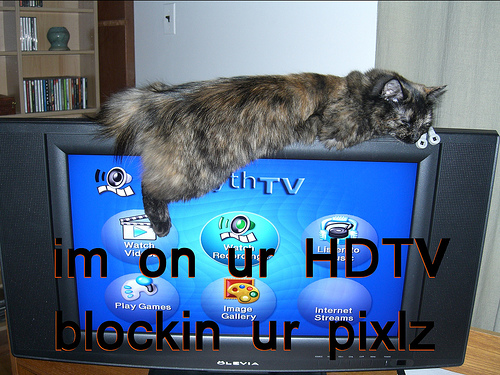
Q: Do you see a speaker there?
A: Yes, there is a speaker.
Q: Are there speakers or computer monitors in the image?
A: Yes, there is a speaker.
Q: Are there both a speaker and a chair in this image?
A: No, there is a speaker but no chairs.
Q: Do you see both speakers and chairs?
A: No, there is a speaker but no chairs.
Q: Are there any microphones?
A: No, there are no microphones.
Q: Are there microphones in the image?
A: No, there are no microphones.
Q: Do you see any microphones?
A: No, there are no microphones.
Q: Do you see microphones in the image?
A: No, there are no microphones.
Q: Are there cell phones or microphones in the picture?
A: No, there are no microphones or cell phones.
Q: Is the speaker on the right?
A: Yes, the speaker is on the right of the image.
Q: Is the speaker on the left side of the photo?
A: No, the speaker is on the right of the image.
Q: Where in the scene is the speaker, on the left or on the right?
A: The speaker is on the right of the image.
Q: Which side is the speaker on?
A: The speaker is on the right of the image.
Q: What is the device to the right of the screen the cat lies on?
A: The device is a speaker.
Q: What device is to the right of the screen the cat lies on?
A: The device is a speaker.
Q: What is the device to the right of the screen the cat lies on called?
A: The device is a speaker.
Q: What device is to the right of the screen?
A: The device is a speaker.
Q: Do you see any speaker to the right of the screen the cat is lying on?
A: Yes, there is a speaker to the right of the screen.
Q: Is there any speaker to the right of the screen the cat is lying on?
A: Yes, there is a speaker to the right of the screen.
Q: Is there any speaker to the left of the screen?
A: No, the speaker is to the right of the screen.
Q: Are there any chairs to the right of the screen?
A: No, there is a speaker to the right of the screen.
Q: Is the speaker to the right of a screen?
A: Yes, the speaker is to the right of a screen.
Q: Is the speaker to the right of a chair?
A: No, the speaker is to the right of a screen.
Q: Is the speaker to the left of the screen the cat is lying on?
A: No, the speaker is to the right of the screen.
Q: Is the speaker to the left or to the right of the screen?
A: The speaker is to the right of the screen.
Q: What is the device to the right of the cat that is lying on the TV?
A: The device is a speaker.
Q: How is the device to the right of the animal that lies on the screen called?
A: The device is a speaker.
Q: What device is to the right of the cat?
A: The device is a speaker.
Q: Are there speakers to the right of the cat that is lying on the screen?
A: Yes, there is a speaker to the right of the cat.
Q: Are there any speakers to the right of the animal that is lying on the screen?
A: Yes, there is a speaker to the right of the cat.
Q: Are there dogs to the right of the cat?
A: No, there is a speaker to the right of the cat.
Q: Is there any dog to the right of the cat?
A: No, there is a speaker to the right of the cat.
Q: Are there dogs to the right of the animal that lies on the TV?
A: No, there is a speaker to the right of the cat.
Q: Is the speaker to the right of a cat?
A: Yes, the speaker is to the right of a cat.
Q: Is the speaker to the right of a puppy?
A: No, the speaker is to the right of a cat.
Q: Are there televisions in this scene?
A: Yes, there is a television.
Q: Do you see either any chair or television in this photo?
A: Yes, there is a television.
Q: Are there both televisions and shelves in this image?
A: Yes, there are both a television and a shelf.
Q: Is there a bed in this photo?
A: No, there are no beds.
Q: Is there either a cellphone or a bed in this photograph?
A: No, there are no beds or cell phones.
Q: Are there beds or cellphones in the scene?
A: No, there are no beds or cellphones.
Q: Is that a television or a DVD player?
A: That is a television.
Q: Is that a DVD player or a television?
A: That is a television.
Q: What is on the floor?
A: The television is on the floor.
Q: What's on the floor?
A: The television is on the floor.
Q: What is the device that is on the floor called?
A: The device is a television.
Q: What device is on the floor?
A: The device is a television.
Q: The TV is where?
A: The TV is on the floor.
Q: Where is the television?
A: The TV is on the floor.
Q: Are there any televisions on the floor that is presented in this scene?
A: Yes, there is a television on the floor.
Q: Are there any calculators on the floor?
A: No, there is a television on the floor.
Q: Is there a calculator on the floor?
A: No, there is a television on the floor.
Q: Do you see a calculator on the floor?
A: No, there is a television on the floor.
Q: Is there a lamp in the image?
A: No, there are no lamps.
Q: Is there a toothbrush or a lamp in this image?
A: No, there are no lamps or toothbrushes.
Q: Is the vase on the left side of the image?
A: Yes, the vase is on the left of the image.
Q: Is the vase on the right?
A: No, the vase is on the left of the image.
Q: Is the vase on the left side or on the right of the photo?
A: The vase is on the left of the image.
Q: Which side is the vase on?
A: The vase is on the left of the image.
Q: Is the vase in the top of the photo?
A: Yes, the vase is in the top of the image.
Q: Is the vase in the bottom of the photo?
A: No, the vase is in the top of the image.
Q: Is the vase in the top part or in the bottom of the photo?
A: The vase is in the top of the image.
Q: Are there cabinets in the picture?
A: No, there are no cabinets.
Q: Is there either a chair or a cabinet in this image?
A: No, there are no cabinets or chairs.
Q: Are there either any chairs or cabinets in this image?
A: No, there are no cabinets or chairs.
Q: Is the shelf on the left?
A: Yes, the shelf is on the left of the image.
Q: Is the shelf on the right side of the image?
A: No, the shelf is on the left of the image.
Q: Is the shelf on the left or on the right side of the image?
A: The shelf is on the left of the image.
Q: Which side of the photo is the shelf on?
A: The shelf is on the left of the image.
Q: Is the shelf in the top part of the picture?
A: Yes, the shelf is in the top of the image.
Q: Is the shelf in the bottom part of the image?
A: No, the shelf is in the top of the image.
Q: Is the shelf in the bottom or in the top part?
A: The shelf is in the top of the image.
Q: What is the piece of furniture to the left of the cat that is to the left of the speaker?
A: The piece of furniture is a shelf.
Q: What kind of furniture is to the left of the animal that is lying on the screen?
A: The piece of furniture is a shelf.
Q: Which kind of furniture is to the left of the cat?
A: The piece of furniture is a shelf.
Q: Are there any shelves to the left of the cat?
A: Yes, there is a shelf to the left of the cat.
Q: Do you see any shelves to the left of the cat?
A: Yes, there is a shelf to the left of the cat.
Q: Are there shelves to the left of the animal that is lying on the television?
A: Yes, there is a shelf to the left of the cat.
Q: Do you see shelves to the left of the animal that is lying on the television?
A: Yes, there is a shelf to the left of the cat.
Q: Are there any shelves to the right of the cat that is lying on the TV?
A: No, the shelf is to the left of the cat.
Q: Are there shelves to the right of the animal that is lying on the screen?
A: No, the shelf is to the left of the cat.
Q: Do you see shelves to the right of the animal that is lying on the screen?
A: No, the shelf is to the left of the cat.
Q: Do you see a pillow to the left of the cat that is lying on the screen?
A: No, there is a shelf to the left of the cat.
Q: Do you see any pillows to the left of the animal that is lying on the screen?
A: No, there is a shelf to the left of the cat.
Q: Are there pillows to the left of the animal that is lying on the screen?
A: No, there is a shelf to the left of the cat.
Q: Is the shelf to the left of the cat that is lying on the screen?
A: Yes, the shelf is to the left of the cat.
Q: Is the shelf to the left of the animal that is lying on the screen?
A: Yes, the shelf is to the left of the cat.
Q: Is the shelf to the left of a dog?
A: No, the shelf is to the left of the cat.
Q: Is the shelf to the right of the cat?
A: No, the shelf is to the left of the cat.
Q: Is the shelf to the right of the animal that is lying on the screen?
A: No, the shelf is to the left of the cat.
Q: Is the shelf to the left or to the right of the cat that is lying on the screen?
A: The shelf is to the left of the cat.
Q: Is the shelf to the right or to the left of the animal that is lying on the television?
A: The shelf is to the left of the cat.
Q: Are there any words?
A: Yes, there are words.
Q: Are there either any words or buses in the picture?
A: Yes, there are words.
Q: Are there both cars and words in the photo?
A: No, there are words but no cars.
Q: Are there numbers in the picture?
A: No, there are no numbers.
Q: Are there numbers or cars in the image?
A: No, there are no numbers or cars.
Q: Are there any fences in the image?
A: No, there are no fences.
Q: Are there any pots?
A: No, there are no pots.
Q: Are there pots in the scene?
A: No, there are no pots.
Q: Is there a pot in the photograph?
A: No, there are no pots.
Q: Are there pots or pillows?
A: No, there are no pots or pillows.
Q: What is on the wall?
A: The switch is on the wall.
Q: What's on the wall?
A: The switch is on the wall.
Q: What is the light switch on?
A: The light switch is on the wall.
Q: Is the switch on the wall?
A: Yes, the switch is on the wall.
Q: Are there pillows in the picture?
A: No, there are no pillows.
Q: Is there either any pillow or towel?
A: No, there are no pillows or towels.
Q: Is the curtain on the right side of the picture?
A: Yes, the curtain is on the right of the image.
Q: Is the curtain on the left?
A: No, the curtain is on the right of the image.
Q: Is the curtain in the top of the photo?
A: Yes, the curtain is in the top of the image.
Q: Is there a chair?
A: No, there are no chairs.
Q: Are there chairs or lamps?
A: No, there are no chairs or lamps.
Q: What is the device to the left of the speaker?
A: The device is a screen.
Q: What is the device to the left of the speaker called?
A: The device is a screen.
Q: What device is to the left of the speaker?
A: The device is a screen.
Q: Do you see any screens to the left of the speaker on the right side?
A: Yes, there is a screen to the left of the speaker.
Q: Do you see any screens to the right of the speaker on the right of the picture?
A: No, the screen is to the left of the speaker.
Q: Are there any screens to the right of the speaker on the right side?
A: No, the screen is to the left of the speaker.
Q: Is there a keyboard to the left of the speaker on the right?
A: No, there is a screen to the left of the speaker.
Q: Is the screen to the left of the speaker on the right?
A: Yes, the screen is to the left of the speaker.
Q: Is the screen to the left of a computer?
A: No, the screen is to the left of the speaker.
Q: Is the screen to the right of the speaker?
A: No, the screen is to the left of the speaker.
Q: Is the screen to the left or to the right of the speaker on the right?
A: The screen is to the left of the speaker.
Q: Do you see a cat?
A: Yes, there is a cat.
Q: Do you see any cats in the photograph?
A: Yes, there is a cat.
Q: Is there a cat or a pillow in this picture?
A: Yes, there is a cat.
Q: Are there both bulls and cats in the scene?
A: No, there is a cat but no bulls.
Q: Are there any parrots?
A: No, there are no parrots.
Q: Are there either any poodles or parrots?
A: No, there are no parrots or poodles.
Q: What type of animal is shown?
A: The animal is a cat.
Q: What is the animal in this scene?
A: The animal is a cat.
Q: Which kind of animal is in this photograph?
A: The animal is a cat.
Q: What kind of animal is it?
A: The animal is a cat.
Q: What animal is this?
A: This is a cat.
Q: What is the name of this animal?
A: This is a cat.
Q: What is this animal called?
A: This is a cat.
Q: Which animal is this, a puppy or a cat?
A: This is a cat.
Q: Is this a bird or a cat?
A: This is a cat.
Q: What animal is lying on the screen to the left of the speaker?
A: The cat is lying on the screen.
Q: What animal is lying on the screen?
A: The cat is lying on the screen.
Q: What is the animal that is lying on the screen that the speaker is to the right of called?
A: The animal is a cat.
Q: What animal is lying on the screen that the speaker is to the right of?
A: The animal is a cat.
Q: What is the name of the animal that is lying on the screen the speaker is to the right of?
A: The animal is a cat.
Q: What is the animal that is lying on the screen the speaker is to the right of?
A: The animal is a cat.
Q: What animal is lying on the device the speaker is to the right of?
A: The animal is a cat.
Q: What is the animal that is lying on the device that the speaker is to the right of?
A: The animal is a cat.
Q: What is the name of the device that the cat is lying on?
A: The device is a screen.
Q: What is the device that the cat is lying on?
A: The device is a screen.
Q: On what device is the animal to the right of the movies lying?
A: The cat is lying on the screen.